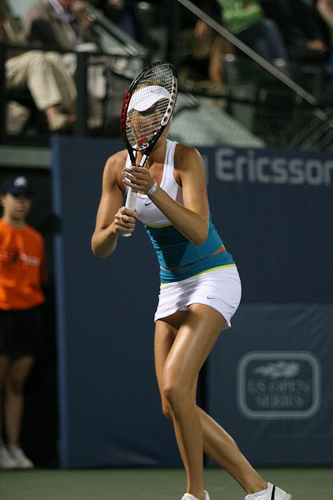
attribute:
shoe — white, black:
[244, 483, 292, 499]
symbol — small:
[191, 283, 229, 316]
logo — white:
[230, 344, 326, 423]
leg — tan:
[151, 305, 264, 484]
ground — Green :
[301, 110, 322, 127]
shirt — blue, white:
[124, 137, 236, 283]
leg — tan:
[158, 266, 239, 498]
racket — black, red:
[121, 60, 187, 147]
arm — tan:
[121, 148, 219, 237]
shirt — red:
[0, 216, 47, 312]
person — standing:
[0, 166, 63, 476]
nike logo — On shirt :
[130, 197, 169, 218]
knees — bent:
[155, 379, 180, 422]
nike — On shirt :
[129, 189, 164, 216]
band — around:
[143, 175, 160, 197]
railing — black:
[1, 1, 332, 148]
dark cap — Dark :
[1, 173, 33, 197]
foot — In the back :
[244, 481, 293, 499]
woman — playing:
[62, 63, 284, 432]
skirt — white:
[148, 269, 237, 318]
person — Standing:
[0, 170, 52, 469]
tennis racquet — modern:
[111, 59, 182, 239]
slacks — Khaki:
[0, 47, 77, 109]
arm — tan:
[82, 161, 113, 252]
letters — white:
[216, 149, 332, 187]